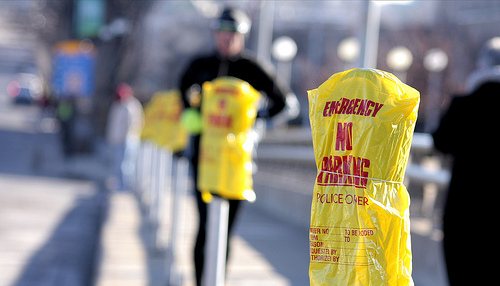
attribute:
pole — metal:
[203, 194, 230, 283]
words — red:
[317, 97, 384, 191]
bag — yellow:
[296, 61, 425, 283]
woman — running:
[176, 2, 289, 274]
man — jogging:
[183, 10, 289, 255]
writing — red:
[312, 97, 393, 208]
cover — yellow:
[292, 67, 415, 283]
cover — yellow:
[196, 73, 264, 205]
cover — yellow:
[154, 86, 181, 142]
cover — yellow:
[140, 86, 160, 142]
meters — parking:
[137, 70, 419, 283]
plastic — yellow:
[304, 66, 424, 285]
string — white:
[312, 166, 408, 186]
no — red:
[333, 115, 360, 155]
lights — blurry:
[253, 8, 478, 85]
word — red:
[315, 94, 385, 191]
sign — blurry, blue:
[40, 27, 124, 119]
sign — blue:
[51, 51, 94, 100]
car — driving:
[6, 74, 43, 101]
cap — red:
[117, 84, 131, 101]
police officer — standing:
[178, 4, 287, 283]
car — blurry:
[7, 73, 45, 106]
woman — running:
[169, 5, 292, 281]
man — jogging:
[176, 6, 295, 281]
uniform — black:
[174, 47, 299, 283]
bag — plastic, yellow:
[306, 60, 402, 280]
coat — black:
[432, 77, 497, 282]